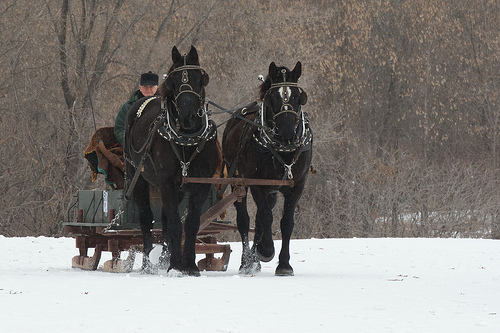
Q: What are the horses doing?
A: Pulling a sleigh.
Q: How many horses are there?
A: Two.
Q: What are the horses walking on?
A: Snow.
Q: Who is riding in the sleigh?
A: A man.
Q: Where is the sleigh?
A: Behind the horses.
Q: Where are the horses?
A: In front of sleigh.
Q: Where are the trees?
A: Background.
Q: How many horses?
A: 2.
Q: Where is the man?
A: On the sleigh.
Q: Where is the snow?
A: On the ground.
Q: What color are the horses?
A: Black.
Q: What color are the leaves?
A: Brown.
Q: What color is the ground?
A: White.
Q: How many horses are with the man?
A: Two.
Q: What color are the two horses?
A: Black.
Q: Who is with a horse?
A: A man.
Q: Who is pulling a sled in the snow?
A: Horses.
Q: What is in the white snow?
A: Spots.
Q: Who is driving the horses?
A: A man.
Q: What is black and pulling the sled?
A: Horses.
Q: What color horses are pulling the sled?
A: Black.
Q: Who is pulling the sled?
A: Black horses.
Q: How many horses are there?
A: 2.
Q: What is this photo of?
A: Black horses pulling the sled.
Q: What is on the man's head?
A: A hat.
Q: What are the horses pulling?
A: A sled.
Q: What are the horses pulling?
A: A sled.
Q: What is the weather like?
A: Overcast.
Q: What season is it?
A: Winter.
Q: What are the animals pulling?
A: A sleigh.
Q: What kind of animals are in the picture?
A: Horses.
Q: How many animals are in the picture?
A: Two.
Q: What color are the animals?
A: Black.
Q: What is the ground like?
A: Snowy.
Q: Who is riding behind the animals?
A: A man.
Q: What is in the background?
A: Trees.